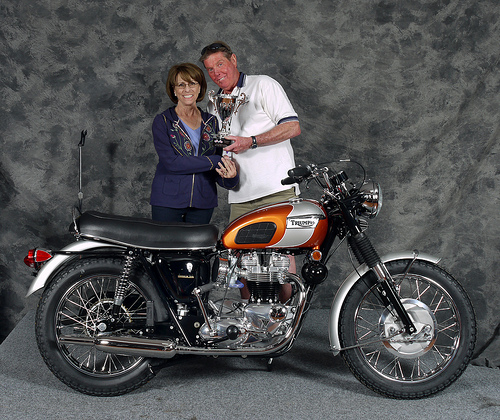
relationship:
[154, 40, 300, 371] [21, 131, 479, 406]
people by motorcycle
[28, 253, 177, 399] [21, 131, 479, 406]
wheel on motorcycle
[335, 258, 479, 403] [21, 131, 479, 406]
wheel on motorcycle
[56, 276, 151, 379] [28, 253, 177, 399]
spokes on wheel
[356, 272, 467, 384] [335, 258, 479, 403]
spokes on wheel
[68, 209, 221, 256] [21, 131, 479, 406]
seat on motorcycle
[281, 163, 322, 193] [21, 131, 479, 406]
handles on motorcycle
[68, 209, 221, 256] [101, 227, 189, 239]
seat on bike leather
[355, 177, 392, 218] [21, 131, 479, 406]
light on motorcycle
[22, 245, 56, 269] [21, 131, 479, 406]
light on motorcycle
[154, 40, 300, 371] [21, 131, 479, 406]
people near motorcycle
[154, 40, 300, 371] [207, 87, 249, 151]
people holding trophy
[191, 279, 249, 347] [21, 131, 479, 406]
pedal on motorcycle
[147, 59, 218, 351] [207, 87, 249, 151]
woman posing with a trophy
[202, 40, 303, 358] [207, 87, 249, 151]
man posing with a trophy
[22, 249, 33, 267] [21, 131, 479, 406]
brake light on motorcycle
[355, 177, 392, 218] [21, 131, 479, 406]
light on front of motorcycle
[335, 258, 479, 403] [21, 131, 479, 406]
wheel on front of motorcycle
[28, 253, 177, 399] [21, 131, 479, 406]
wheel on back of motorcycle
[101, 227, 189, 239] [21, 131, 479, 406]
leather seat on motorcycle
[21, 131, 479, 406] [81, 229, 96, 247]
motorcycle orange silver, and black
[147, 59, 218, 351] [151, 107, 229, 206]
woman wearing blue jacket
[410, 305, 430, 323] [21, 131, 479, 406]
chrome on front wheel of motorcycle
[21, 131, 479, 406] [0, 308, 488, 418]
motorcycle on gray carpet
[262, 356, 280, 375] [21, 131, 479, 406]
chrome kickstand on motorcycle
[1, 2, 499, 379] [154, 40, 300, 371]
gray backdrop behind people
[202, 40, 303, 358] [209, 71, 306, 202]
man wearing white shirt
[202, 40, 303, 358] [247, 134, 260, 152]
man wearing black watch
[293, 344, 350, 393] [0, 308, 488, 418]
shadow on gray carpet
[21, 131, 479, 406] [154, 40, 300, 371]
motorcycle near people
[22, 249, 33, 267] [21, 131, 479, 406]
brake light of motorcycle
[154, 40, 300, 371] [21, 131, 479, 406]
people standing near motorcycle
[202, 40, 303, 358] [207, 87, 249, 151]
man holding trophy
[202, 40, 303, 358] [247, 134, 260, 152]
man has a black watch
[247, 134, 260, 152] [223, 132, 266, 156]
black watch on left hand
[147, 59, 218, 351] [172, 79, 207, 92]
woman wearing glasses